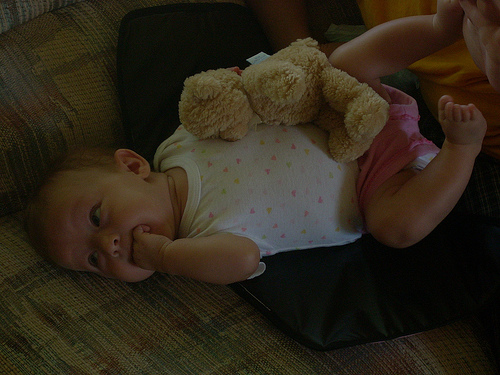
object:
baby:
[24, 3, 489, 287]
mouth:
[129, 221, 144, 269]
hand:
[132, 223, 166, 273]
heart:
[263, 167, 272, 176]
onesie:
[152, 123, 362, 280]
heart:
[234, 157, 243, 166]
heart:
[316, 195, 325, 206]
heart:
[205, 159, 214, 169]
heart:
[290, 188, 298, 199]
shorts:
[349, 78, 443, 205]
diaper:
[402, 151, 443, 174]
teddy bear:
[178, 37, 390, 162]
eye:
[88, 200, 108, 229]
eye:
[85, 248, 102, 270]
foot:
[436, 93, 488, 146]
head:
[22, 147, 176, 283]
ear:
[114, 148, 151, 180]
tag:
[246, 50, 270, 66]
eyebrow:
[68, 196, 83, 230]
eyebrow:
[68, 245, 81, 273]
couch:
[1, 0, 499, 374]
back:
[181, 236, 378, 253]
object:
[116, 0, 273, 158]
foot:
[434, 0, 468, 40]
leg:
[327, 15, 443, 90]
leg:
[366, 150, 479, 250]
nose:
[100, 233, 122, 258]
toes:
[437, 94, 454, 119]